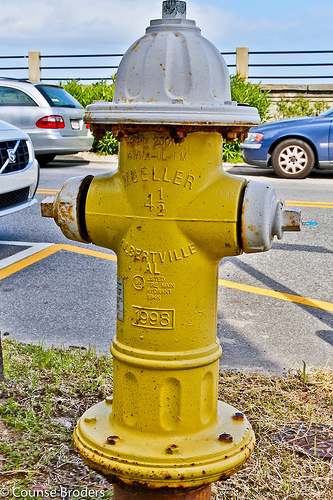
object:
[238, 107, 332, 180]
car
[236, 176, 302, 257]
outlet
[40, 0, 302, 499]
fire hydrant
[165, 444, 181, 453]
bolts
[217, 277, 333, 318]
lines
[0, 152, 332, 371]
road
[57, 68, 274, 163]
grass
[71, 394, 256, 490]
plate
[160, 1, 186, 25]
cap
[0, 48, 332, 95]
railing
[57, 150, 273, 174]
sidewalk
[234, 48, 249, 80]
post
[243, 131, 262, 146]
headlight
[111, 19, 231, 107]
lid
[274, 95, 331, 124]
shrubbery